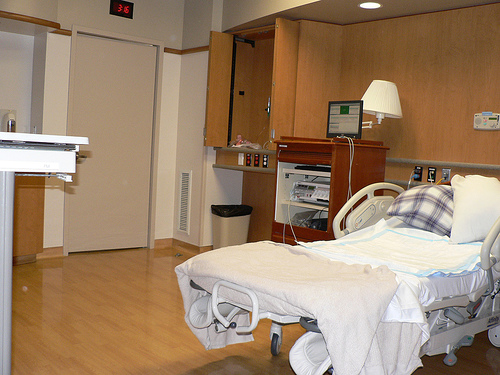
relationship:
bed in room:
[168, 179, 499, 372] [0, 1, 498, 373]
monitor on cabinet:
[325, 98, 365, 139] [269, 131, 391, 244]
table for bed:
[0, 129, 90, 374] [168, 179, 499, 372]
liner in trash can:
[212, 202, 255, 217] [209, 203, 255, 246]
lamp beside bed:
[360, 77, 405, 131] [168, 179, 499, 372]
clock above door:
[108, 1, 135, 21] [62, 24, 167, 257]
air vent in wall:
[177, 166, 195, 236] [174, 4, 244, 245]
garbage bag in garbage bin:
[212, 202, 255, 217] [209, 203, 255, 246]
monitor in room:
[325, 98, 365, 139] [0, 1, 498, 373]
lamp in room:
[360, 77, 405, 131] [0, 1, 498, 373]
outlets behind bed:
[411, 163, 455, 186] [168, 179, 499, 372]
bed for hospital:
[168, 179, 499, 372] [0, 1, 498, 373]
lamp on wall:
[360, 77, 405, 131] [296, 2, 498, 197]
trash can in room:
[209, 203, 255, 246] [0, 1, 498, 373]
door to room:
[62, 24, 167, 257] [0, 1, 498, 373]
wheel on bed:
[267, 322, 284, 360] [168, 179, 499, 372]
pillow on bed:
[444, 172, 500, 244] [168, 179, 499, 372]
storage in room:
[196, 17, 295, 173] [0, 1, 498, 373]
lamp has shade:
[360, 77, 405, 131] [360, 78, 404, 118]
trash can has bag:
[209, 203, 255, 246] [212, 202, 255, 217]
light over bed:
[357, 0, 384, 14] [168, 179, 499, 372]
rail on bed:
[329, 180, 406, 241] [168, 179, 499, 372]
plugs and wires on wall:
[401, 158, 456, 194] [296, 2, 498, 197]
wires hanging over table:
[334, 131, 357, 234] [269, 131, 391, 244]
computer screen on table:
[325, 98, 365, 139] [269, 131, 391, 244]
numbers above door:
[116, 3, 130, 14] [62, 24, 167, 257]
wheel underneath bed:
[267, 322, 284, 360] [168, 179, 499, 372]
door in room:
[62, 24, 167, 257] [0, 1, 498, 373]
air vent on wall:
[177, 166, 195, 236] [174, 4, 244, 245]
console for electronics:
[269, 131, 391, 244] [273, 100, 364, 230]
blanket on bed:
[171, 238, 429, 374] [168, 179, 499, 372]